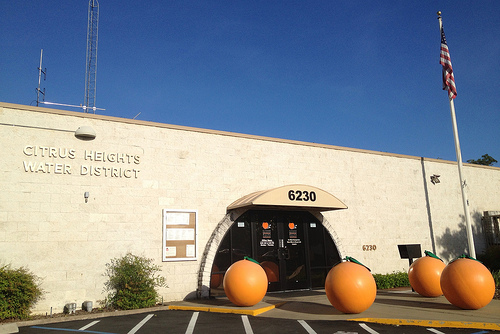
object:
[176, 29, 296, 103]
sky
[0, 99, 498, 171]
brown edge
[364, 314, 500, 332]
paint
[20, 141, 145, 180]
words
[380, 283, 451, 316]
shadow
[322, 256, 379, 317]
fruit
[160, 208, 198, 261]
announcement board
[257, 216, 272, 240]
sign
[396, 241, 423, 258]
mailbox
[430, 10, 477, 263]
flag pole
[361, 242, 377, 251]
number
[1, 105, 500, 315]
wall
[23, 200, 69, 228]
paint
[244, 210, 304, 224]
frame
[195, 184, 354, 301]
door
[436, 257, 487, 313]
orange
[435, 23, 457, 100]
flag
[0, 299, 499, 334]
ground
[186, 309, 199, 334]
line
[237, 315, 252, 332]
line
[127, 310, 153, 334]
line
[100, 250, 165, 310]
bush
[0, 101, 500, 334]
building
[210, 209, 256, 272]
glass